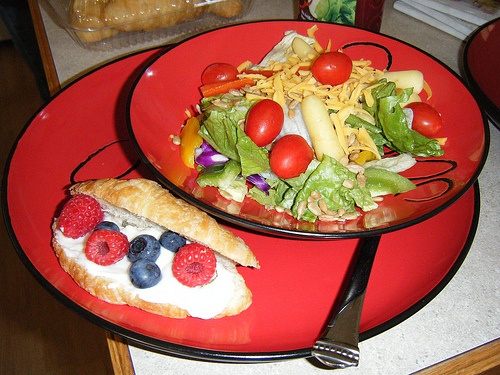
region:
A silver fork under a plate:
[310, 233, 392, 373]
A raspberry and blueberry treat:
[32, 168, 261, 326]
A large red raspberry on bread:
[171, 241, 216, 292]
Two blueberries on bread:
[126, 230, 161, 291]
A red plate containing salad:
[121, 16, 498, 243]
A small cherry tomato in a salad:
[241, 100, 286, 147]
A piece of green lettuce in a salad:
[296, 160, 418, 223]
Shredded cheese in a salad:
[253, 53, 382, 108]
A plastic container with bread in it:
[58, 0, 265, 58]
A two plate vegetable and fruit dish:
[2, 16, 493, 358]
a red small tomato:
[302, 49, 356, 86]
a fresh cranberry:
[172, 237, 218, 288]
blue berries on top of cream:
[125, 228, 184, 290]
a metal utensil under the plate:
[294, 215, 403, 371]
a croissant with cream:
[39, 167, 259, 319]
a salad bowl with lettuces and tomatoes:
[115, 5, 485, 232]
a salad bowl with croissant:
[10, 7, 485, 366]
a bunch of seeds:
[200, 19, 405, 169]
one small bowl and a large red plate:
[5, 14, 485, 361]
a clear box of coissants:
[30, 0, 264, 52]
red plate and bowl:
[13, 23, 483, 364]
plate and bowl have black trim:
[23, 2, 473, 362]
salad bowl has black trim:
[329, 35, 463, 227]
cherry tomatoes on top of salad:
[244, 89, 316, 187]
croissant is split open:
[51, 145, 263, 346]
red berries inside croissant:
[56, 177, 128, 277]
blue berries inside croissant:
[120, 230, 165, 282]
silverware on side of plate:
[295, 237, 383, 372]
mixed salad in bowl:
[181, 35, 456, 206]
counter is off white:
[424, 270, 497, 347]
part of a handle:
[345, 282, 371, 330]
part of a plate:
[261, 305, 281, 342]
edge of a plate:
[224, 323, 266, 368]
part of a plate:
[291, 295, 316, 337]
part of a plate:
[238, 333, 270, 363]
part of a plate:
[268, 280, 282, 310]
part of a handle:
[326, 257, 372, 339]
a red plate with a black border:
[128, 16, 489, 240]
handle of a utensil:
[306, 232, 383, 372]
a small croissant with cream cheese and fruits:
[48, 173, 258, 316]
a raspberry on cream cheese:
[57, 192, 104, 239]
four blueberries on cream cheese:
[96, 218, 183, 290]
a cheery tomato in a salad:
[246, 96, 282, 145]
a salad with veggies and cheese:
[181, 28, 448, 224]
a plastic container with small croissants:
[38, 0, 250, 47]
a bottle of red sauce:
[295, 1, 382, 32]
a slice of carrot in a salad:
[201, 75, 253, 97]